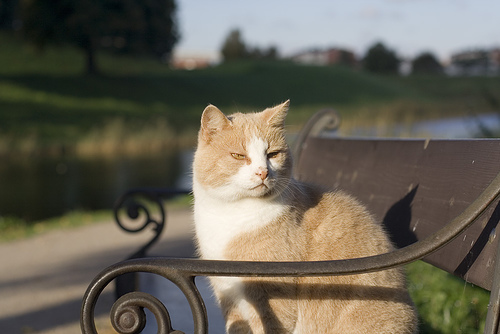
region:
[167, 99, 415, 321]
cat sitting in the bench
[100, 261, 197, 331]
scrollwork on the bench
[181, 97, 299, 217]
head of the bench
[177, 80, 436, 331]
cat on a bench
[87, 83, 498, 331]
cat sitting on bench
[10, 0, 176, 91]
tree on green grass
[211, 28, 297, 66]
several trees on hill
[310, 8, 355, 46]
clear blue sky with light clouds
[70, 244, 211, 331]
iron arm on chair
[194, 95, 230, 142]
ear of golden cat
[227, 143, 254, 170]
eye of cat golden fur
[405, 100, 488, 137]
stream of water by grass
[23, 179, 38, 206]
Small ripples in the water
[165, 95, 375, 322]
Ornage and white tabby cat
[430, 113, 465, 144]
Small ripples in the water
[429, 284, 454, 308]
Patch of green grass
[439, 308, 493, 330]
Patch of green grass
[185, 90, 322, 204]
head of a cat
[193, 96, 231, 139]
ear of a cat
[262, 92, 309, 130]
ear of a cat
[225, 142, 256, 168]
eye of a cat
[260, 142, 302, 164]
eye of a cat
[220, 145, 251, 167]
an eye of a cat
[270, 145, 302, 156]
an eye of a cat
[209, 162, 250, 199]
whisker of a cat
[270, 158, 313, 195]
whisker of a cat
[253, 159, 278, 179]
nose of a cat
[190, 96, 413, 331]
orange and white cat on a bench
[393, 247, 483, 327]
green pillow against a bench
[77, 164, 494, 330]
metal curved design on the bench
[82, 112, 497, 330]
black metal bench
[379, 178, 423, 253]
shadow from the cat on the bench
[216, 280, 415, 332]
shadow of the bench on the cat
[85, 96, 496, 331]
the cat and front portion of the bench are in focus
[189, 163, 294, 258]
white neck and belly on the cat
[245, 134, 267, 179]
the cat has a white nose